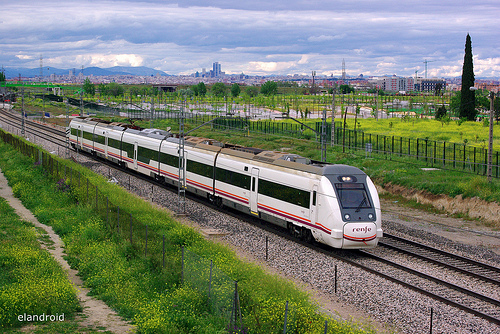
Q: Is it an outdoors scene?
A: Yes, it is outdoors.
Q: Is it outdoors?
A: Yes, it is outdoors.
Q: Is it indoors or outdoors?
A: It is outdoors.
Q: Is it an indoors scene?
A: No, it is outdoors.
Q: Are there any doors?
A: Yes, there is a door.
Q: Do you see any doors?
A: Yes, there is a door.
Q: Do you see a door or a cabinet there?
A: Yes, there is a door.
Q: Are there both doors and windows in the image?
A: Yes, there are both a door and a window.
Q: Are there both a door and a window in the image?
A: Yes, there are both a door and a window.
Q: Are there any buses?
A: No, there are no buses.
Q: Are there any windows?
A: Yes, there are windows.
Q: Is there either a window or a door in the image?
A: Yes, there are windows.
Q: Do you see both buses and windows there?
A: No, there are windows but no buses.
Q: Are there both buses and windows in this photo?
A: No, there are windows but no buses.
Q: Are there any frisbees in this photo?
A: No, there are no frisbees.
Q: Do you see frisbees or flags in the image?
A: No, there are no frisbees or flags.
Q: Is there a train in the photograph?
A: Yes, there is a train.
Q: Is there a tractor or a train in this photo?
A: Yes, there is a train.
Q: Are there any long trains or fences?
A: Yes, there is a long train.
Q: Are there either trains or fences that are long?
A: Yes, the train is long.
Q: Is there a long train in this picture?
A: Yes, there is a long train.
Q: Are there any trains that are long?
A: Yes, there is a train that is long.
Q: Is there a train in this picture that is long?
A: Yes, there is a train that is long.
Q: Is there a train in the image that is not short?
A: Yes, there is a long train.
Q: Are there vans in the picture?
A: No, there are no vans.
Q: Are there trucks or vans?
A: No, there are no vans or trucks.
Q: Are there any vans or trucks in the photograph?
A: No, there are no vans or trucks.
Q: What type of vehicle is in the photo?
A: The vehicle is a train.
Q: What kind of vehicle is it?
A: The vehicle is a train.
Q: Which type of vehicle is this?
A: This is a train.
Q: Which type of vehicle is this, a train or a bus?
A: This is a train.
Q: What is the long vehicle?
A: The vehicle is a train.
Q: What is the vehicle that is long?
A: The vehicle is a train.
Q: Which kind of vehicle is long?
A: The vehicle is a train.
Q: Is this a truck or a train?
A: This is a train.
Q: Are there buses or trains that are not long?
A: No, there is a train but it is long.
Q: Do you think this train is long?
A: Yes, the train is long.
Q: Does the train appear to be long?
A: Yes, the train is long.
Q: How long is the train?
A: The train is long.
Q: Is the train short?
A: No, the train is long.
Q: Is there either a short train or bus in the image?
A: No, there is a train but it is long.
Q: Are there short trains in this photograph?
A: No, there is a train but it is long.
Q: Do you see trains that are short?
A: No, there is a train but it is long.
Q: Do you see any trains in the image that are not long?
A: No, there is a train but it is long.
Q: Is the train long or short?
A: The train is long.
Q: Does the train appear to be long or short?
A: The train is long.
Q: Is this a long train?
A: Yes, this is a long train.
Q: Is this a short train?
A: No, this is a long train.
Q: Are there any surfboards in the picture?
A: No, there are no surfboards.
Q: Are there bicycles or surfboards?
A: No, there are no surfboards or bicycles.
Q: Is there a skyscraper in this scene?
A: Yes, there is a skyscraper.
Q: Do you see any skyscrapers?
A: Yes, there is a skyscraper.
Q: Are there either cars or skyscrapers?
A: Yes, there is a skyscraper.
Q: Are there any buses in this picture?
A: No, there are no buses.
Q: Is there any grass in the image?
A: Yes, there is grass.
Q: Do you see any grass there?
A: Yes, there is grass.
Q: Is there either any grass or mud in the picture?
A: Yes, there is grass.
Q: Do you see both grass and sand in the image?
A: No, there is grass but no sand.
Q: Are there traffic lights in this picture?
A: No, there are no traffic lights.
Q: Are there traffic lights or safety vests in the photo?
A: No, there are no traffic lights or safety vests.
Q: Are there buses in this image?
A: No, there are no buses.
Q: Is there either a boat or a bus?
A: No, there are no buses or boats.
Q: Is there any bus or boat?
A: No, there are no buses or boats.